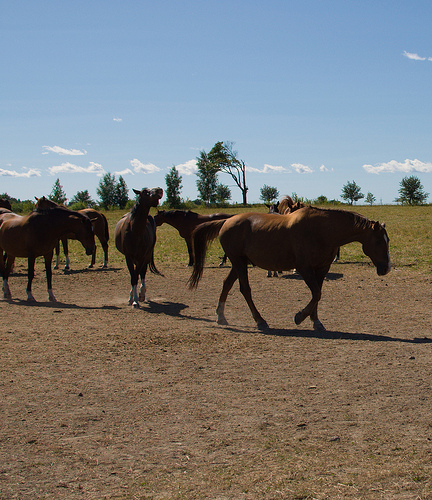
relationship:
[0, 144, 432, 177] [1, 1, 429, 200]
cloud in sky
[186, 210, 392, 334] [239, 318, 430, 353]
horse has shadow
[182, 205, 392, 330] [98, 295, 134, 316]
horse in dirt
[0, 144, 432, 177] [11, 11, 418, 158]
cloud in sky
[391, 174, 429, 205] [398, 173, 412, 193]
leafy tree has leaves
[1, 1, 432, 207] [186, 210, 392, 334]
sky on horse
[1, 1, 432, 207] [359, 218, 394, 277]
sky on head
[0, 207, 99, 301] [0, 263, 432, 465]
horse on field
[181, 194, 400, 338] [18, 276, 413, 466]
horse on field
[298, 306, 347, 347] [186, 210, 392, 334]
hoove on horse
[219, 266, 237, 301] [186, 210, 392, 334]
back legs on horse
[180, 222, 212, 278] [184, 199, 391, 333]
tail on horse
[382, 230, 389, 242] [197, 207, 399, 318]
spot on horse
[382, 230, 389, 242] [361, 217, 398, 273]
spot on head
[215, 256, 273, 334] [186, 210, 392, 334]
back legs of horse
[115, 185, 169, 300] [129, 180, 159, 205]
horse has head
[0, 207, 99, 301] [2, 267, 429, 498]
horse walking on dirt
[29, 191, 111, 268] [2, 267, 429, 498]
horse walking on dirt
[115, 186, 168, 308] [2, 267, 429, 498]
horse walking on dirt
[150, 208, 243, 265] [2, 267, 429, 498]
horse walking on dirt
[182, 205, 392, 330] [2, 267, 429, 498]
horse walking on dirt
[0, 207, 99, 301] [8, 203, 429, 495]
horse walking on dirt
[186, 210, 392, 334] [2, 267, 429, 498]
horse walking on dirt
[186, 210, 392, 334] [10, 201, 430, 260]
horse standing in field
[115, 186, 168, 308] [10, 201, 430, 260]
horse standing in field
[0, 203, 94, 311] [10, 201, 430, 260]
horse standing in field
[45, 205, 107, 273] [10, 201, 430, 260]
horse standing in field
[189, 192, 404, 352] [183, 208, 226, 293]
horse has tail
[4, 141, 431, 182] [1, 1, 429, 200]
cloud in sky